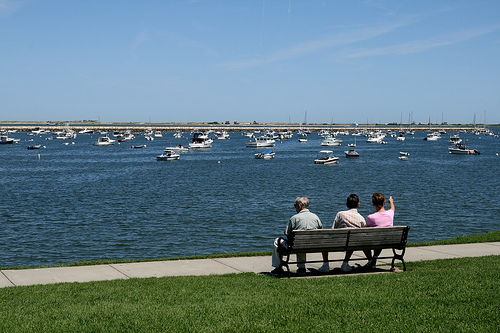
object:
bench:
[278, 223, 415, 276]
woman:
[364, 193, 397, 273]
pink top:
[366, 209, 396, 229]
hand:
[388, 196, 395, 203]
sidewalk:
[0, 241, 500, 292]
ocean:
[0, 123, 496, 261]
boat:
[244, 135, 276, 147]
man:
[268, 191, 329, 279]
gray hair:
[295, 197, 311, 208]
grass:
[0, 251, 498, 332]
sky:
[2, 3, 495, 122]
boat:
[26, 144, 42, 149]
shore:
[0, 230, 500, 329]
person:
[318, 193, 369, 274]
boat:
[93, 135, 116, 146]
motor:
[118, 142, 120, 144]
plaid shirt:
[331, 208, 369, 228]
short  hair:
[371, 192, 384, 207]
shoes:
[270, 268, 286, 276]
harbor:
[0, 121, 477, 134]